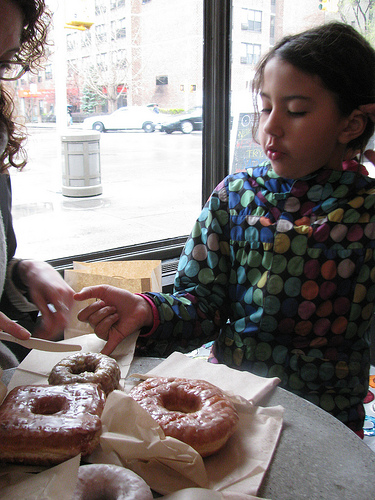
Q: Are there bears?
A: No, there are no bears.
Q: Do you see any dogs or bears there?
A: No, there are no bears or dogs.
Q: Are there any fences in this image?
A: No, there are no fences.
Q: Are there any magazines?
A: No, there are no magazines.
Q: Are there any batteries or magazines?
A: No, there are no magazines or batteries.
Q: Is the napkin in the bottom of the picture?
A: Yes, the napkin is in the bottom of the image.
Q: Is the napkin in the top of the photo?
A: No, the napkin is in the bottom of the image.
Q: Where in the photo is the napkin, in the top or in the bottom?
A: The napkin is in the bottom of the image.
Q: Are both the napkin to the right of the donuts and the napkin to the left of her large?
A: Yes, both the napkin and the napkin are large.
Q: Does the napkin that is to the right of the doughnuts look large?
A: Yes, the napkin is large.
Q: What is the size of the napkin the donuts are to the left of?
A: The napkin is large.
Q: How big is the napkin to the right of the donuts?
A: The napkin is large.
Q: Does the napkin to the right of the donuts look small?
A: No, the napkin is large.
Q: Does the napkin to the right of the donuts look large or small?
A: The napkin is large.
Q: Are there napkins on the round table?
A: Yes, there is a napkin on the table.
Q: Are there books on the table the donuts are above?
A: No, there is a napkin on the table.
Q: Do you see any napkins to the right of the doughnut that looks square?
A: Yes, there is a napkin to the right of the doughnut.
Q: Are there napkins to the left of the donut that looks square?
A: No, the napkin is to the right of the donut.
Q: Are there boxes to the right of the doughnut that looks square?
A: No, there is a napkin to the right of the doughnut.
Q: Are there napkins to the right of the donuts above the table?
A: Yes, there is a napkin to the right of the doughnuts.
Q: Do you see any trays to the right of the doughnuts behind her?
A: No, there is a napkin to the right of the doughnuts.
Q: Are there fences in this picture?
A: No, there are no fences.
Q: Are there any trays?
A: No, there are no trays.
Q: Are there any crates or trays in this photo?
A: No, there are no trays or crates.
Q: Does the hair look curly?
A: Yes, the hair is curly.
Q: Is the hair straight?
A: No, the hair is curly.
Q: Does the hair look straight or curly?
A: The hair is curly.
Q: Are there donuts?
A: Yes, there are donuts.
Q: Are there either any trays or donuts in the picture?
A: Yes, there are donuts.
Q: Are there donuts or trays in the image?
A: Yes, there are donuts.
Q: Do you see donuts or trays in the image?
A: Yes, there are donuts.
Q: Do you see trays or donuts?
A: Yes, there are donuts.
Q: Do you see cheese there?
A: No, there is no cheese.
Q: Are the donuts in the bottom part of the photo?
A: Yes, the donuts are in the bottom of the image.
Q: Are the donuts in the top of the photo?
A: No, the donuts are in the bottom of the image.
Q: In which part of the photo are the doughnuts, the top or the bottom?
A: The doughnuts are in the bottom of the image.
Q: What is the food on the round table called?
A: The food is donuts.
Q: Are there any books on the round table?
A: No, there are donuts on the table.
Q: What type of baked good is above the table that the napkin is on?
A: The food is donuts.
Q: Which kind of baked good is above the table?
A: The food is donuts.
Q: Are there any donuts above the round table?
A: Yes, there are donuts above the table.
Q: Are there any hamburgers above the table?
A: No, there are donuts above the table.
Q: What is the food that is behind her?
A: The food is donuts.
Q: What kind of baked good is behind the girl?
A: The food is donuts.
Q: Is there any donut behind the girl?
A: Yes, there are donuts behind the girl.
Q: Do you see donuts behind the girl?
A: Yes, there are donuts behind the girl.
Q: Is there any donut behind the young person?
A: Yes, there are donuts behind the girl.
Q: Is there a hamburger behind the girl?
A: No, there are donuts behind the girl.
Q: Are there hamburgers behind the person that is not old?
A: No, there are donuts behind the girl.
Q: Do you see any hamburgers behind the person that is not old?
A: No, there are donuts behind the girl.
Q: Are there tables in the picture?
A: Yes, there is a table.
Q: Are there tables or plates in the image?
A: Yes, there is a table.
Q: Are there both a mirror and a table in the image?
A: No, there is a table but no mirrors.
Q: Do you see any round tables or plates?
A: Yes, there is a round table.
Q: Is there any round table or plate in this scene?
A: Yes, there is a round table.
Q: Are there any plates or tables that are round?
A: Yes, the table is round.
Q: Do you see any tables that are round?
A: Yes, there is a round table.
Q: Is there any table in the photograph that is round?
A: Yes, there is a table that is round.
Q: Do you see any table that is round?
A: Yes, there is a table that is round.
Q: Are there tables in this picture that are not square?
A: Yes, there is a round table.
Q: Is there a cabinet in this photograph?
A: No, there are no cabinets.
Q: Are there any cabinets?
A: No, there are no cabinets.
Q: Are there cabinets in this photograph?
A: No, there are no cabinets.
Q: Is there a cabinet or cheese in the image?
A: No, there are no cabinets or cheese.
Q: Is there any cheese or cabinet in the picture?
A: No, there are no cabinets or cheese.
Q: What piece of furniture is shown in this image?
A: The piece of furniture is a table.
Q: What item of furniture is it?
A: The piece of furniture is a table.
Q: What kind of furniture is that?
A: This is a table.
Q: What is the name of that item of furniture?
A: This is a table.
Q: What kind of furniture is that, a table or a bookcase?
A: This is a table.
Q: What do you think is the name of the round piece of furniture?
A: The piece of furniture is a table.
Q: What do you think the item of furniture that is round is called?
A: The piece of furniture is a table.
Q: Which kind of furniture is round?
A: The furniture is a table.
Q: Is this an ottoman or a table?
A: This is a table.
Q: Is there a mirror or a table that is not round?
A: No, there is a table but it is round.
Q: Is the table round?
A: Yes, the table is round.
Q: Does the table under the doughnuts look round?
A: Yes, the table is round.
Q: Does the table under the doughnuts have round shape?
A: Yes, the table is round.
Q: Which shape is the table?
A: The table is round.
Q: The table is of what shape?
A: The table is round.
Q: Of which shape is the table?
A: The table is round.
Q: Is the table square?
A: No, the table is round.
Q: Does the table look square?
A: No, the table is round.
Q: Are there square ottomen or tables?
A: No, there is a table but it is round.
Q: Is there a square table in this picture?
A: No, there is a table but it is round.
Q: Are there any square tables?
A: No, there is a table but it is round.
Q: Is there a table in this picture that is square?
A: No, there is a table but it is round.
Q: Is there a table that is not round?
A: No, there is a table but it is round.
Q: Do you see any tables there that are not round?
A: No, there is a table but it is round.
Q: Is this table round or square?
A: The table is round.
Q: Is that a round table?
A: Yes, that is a round table.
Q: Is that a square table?
A: No, that is a round table.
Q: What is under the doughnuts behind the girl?
A: The table is under the donuts.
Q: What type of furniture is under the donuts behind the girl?
A: The piece of furniture is a table.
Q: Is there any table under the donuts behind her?
A: Yes, there is a table under the donuts.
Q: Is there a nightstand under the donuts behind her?
A: No, there is a table under the donuts.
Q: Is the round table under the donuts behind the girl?
A: Yes, the table is under the doughnuts.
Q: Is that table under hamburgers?
A: No, the table is under the doughnuts.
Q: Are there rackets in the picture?
A: No, there are no rackets.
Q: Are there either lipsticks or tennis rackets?
A: No, there are no tennis rackets or lipsticks.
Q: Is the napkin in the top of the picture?
A: No, the napkin is in the bottom of the image.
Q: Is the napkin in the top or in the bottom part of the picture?
A: The napkin is in the bottom of the image.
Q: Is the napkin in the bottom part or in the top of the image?
A: The napkin is in the bottom of the image.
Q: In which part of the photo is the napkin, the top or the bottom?
A: The napkin is in the bottom of the image.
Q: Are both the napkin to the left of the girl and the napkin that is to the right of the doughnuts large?
A: Yes, both the napkin and the napkin are large.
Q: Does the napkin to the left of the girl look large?
A: Yes, the napkin is large.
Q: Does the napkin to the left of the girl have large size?
A: Yes, the napkin is large.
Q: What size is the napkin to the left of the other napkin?
A: The napkin is large.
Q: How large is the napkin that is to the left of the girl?
A: The napkin is large.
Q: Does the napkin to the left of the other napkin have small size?
A: No, the napkin is large.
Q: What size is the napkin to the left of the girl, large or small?
A: The napkin is large.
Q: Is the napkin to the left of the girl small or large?
A: The napkin is large.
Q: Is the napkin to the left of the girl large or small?
A: The napkin is large.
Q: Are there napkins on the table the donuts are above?
A: Yes, there is a napkin on the table.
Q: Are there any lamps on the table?
A: No, there is a napkin on the table.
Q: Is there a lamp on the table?
A: No, there is a napkin on the table.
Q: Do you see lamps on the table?
A: No, there is a napkin on the table.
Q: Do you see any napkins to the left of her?
A: Yes, there is a napkin to the left of the girl.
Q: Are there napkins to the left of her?
A: Yes, there is a napkin to the left of the girl.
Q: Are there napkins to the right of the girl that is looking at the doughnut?
A: No, the napkin is to the left of the girl.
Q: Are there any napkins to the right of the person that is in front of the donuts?
A: No, the napkin is to the left of the girl.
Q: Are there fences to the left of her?
A: No, there is a napkin to the left of the girl.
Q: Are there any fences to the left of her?
A: No, there is a napkin to the left of the girl.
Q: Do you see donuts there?
A: Yes, there is a donut.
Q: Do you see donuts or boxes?
A: Yes, there is a donut.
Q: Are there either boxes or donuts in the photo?
A: Yes, there is a donut.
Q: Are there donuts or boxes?
A: Yes, there is a donut.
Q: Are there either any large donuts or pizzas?
A: Yes, there is a large donut.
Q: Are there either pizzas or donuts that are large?
A: Yes, the donut is large.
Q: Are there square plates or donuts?
A: Yes, there is a square donut.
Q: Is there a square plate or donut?
A: Yes, there is a square donut.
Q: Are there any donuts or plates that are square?
A: Yes, the donut is square.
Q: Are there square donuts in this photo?
A: Yes, there is a square donut.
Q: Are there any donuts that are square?
A: Yes, there is a donut that is square.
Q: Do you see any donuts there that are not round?
A: Yes, there is a square donut.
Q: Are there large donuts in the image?
A: Yes, there is a large donut.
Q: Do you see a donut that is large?
A: Yes, there is a large donut.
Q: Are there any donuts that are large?
A: Yes, there is a donut that is large.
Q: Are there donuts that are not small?
A: Yes, there is a large donut.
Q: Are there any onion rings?
A: No, there are no onion rings.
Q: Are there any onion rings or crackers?
A: No, there are no onion rings or crackers.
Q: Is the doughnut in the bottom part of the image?
A: Yes, the doughnut is in the bottom of the image.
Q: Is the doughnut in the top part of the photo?
A: No, the doughnut is in the bottom of the image.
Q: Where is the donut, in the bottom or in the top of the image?
A: The donut is in the bottom of the image.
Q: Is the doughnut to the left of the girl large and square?
A: Yes, the doughnut is large and square.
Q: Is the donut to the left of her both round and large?
A: No, the donut is large but square.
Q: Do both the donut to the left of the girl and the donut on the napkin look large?
A: Yes, both the donut and the doughnut are large.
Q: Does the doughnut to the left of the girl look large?
A: Yes, the doughnut is large.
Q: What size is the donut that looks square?
A: The donut is large.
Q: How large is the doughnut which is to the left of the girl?
A: The doughnut is large.